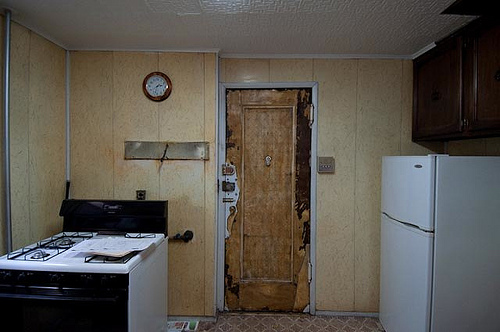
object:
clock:
[140, 70, 174, 102]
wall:
[67, 51, 446, 323]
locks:
[222, 180, 237, 192]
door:
[222, 87, 312, 312]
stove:
[0, 236, 170, 332]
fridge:
[377, 153, 500, 332]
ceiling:
[0, 0, 496, 61]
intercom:
[317, 156, 336, 175]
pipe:
[63, 48, 71, 198]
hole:
[242, 108, 292, 282]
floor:
[182, 310, 387, 332]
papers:
[76, 235, 155, 259]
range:
[0, 268, 130, 332]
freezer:
[378, 153, 499, 332]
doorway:
[217, 80, 319, 316]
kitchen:
[0, 0, 500, 332]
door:
[380, 156, 435, 232]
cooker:
[5, 232, 159, 265]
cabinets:
[407, 14, 498, 142]